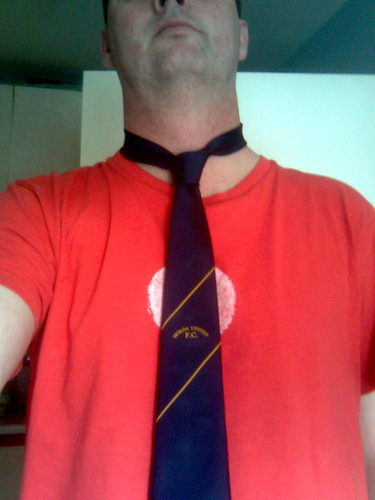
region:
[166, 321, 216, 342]
A logo is written on the neck tie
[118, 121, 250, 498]
The neck tie is navy blue .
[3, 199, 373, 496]
He is wearing a red shirt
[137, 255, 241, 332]
painted white spot behind the tie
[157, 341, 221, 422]
Yellow stripe on tie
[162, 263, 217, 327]
Yellow stripe on tie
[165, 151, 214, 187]
A knot on the neck tie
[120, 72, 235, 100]
Man's chin has stubble beard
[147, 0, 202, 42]
lips and nose only visible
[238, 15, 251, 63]
Only ears visible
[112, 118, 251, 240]
a neck tie on a neck.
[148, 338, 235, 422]
a gold line on a tie.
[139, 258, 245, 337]
a white spot on a shirt.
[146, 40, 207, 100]
a hair chin.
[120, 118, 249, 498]
a dark neck tie around a neck.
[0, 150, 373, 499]
an orange t shirt.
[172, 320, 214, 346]
a logo on a neck tie.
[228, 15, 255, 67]
a left human ear.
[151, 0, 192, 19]
a nose on a human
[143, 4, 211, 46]
a man with mustache stubble.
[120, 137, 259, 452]
The man is wearing a tie.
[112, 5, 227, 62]
The mouth is closed.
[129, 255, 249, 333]
A white circle on shirt.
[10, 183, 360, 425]
The shirt is red.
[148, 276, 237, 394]
The have gold stripes.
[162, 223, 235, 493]
The tie is blue and gold.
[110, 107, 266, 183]
A tie around the man neck.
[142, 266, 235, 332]
The circle is white.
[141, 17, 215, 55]
The mouth is on the man face.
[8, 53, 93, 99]
Dark spots on the wall.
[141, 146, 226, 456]
Man wearing a purple tie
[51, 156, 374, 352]
Man wearing a orange shirt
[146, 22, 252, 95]
man with his chin up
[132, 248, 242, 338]
Orange shirt with purple tie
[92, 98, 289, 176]
Purple tie around man neck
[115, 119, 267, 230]
Purple tie around man neck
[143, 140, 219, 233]
Purple tie around man neck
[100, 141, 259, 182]
Purple tie around man neck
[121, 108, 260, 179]
man using a purple tie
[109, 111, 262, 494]
necktie of blue and gold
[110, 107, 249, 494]
necktie of gold and blue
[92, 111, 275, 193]
necktie on a neck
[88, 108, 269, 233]
necktie without a dress shirt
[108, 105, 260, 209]
necktie with a collared shirt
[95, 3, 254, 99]
man with no facial hair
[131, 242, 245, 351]
white circle behind the tie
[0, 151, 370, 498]
a peach colored t-shirt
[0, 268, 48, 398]
part of the man's right arm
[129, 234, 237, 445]
stripes on a tie